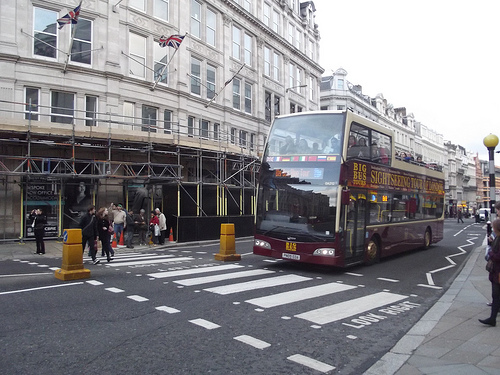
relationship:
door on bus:
[346, 190, 366, 263] [250, 107, 447, 266]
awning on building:
[38, 122, 220, 185] [2, 0, 323, 248]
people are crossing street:
[77, 203, 166, 265] [33, 246, 279, 326]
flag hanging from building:
[152, 31, 189, 49] [2, 0, 323, 248]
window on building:
[32, 4, 63, 59] [2, 0, 323, 248]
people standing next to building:
[77, 203, 166, 265] [2, 0, 323, 248]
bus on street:
[265, 109, 455, 259] [112, 249, 384, 371]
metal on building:
[1, 141, 246, 218] [314, 65, 479, 216]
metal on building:
[1, 141, 246, 218] [2, 0, 323, 248]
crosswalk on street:
[134, 254, 405, 346] [14, 218, 491, 371]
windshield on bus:
[252, 179, 337, 239] [250, 107, 447, 266]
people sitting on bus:
[270, 118, 389, 168] [251, 101, 454, 278]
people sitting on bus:
[71, 198, 171, 264] [251, 101, 454, 278]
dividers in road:
[36, 187, 268, 327] [73, 250, 297, 374]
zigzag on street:
[413, 223, 487, 300] [14, 218, 491, 371]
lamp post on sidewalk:
[479, 119, 498, 331] [357, 191, 498, 373]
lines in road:
[96, 231, 403, 351] [98, 196, 463, 361]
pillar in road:
[48, 224, 91, 281] [3, 198, 483, 373]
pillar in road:
[209, 217, 242, 261] [3, 198, 483, 373]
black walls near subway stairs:
[172, 211, 252, 241] [152, 206, 273, 237]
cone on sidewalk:
[117, 230, 127, 246] [58, 196, 228, 246]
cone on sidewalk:
[109, 227, 119, 250] [58, 196, 228, 246]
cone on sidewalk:
[167, 227, 177, 243] [58, 196, 228, 246]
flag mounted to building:
[52, 0, 86, 76] [2, 0, 323, 248]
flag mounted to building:
[148, 25, 190, 94] [2, 0, 323, 248]